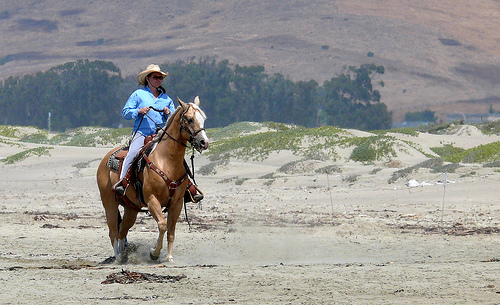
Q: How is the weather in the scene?
A: It is cloudy.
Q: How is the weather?
A: It is cloudy.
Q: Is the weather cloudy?
A: Yes, it is cloudy.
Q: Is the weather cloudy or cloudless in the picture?
A: It is cloudy.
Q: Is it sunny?
A: No, it is cloudy.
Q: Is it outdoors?
A: Yes, it is outdoors.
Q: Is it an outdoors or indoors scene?
A: It is outdoors.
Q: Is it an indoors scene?
A: No, it is outdoors.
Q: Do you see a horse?
A: Yes, there is a horse.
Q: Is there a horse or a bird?
A: Yes, there is a horse.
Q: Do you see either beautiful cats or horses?
A: Yes, there is a beautiful horse.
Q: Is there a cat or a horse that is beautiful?
A: Yes, the horse is beautiful.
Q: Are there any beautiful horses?
A: Yes, there is a beautiful horse.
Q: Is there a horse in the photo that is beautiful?
A: Yes, there is a horse that is beautiful.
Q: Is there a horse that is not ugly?
A: Yes, there is an beautiful horse.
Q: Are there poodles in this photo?
A: No, there are no poodles.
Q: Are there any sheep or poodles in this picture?
A: No, there are no poodles or sheep.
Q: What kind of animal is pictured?
A: The animal is a horse.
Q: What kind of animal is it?
A: The animal is a horse.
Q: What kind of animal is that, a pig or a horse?
A: This is a horse.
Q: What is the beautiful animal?
A: The animal is a horse.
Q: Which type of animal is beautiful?
A: The animal is a horse.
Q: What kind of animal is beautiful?
A: The animal is a horse.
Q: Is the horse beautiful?
A: Yes, the horse is beautiful.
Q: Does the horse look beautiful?
A: Yes, the horse is beautiful.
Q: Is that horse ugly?
A: No, the horse is beautiful.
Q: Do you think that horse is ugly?
A: No, the horse is beautiful.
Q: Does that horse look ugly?
A: No, the horse is beautiful.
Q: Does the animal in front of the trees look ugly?
A: No, the horse is beautiful.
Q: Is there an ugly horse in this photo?
A: No, there is a horse but it is beautiful.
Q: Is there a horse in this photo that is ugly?
A: No, there is a horse but it is beautiful.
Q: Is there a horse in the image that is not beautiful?
A: No, there is a horse but it is beautiful.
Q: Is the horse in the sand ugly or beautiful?
A: The horse is beautiful.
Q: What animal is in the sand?
A: The animal is a horse.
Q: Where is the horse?
A: The horse is in the sand.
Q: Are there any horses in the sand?
A: Yes, there is a horse in the sand.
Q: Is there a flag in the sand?
A: No, there is a horse in the sand.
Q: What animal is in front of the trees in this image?
A: The horse is in front of the trees.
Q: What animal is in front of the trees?
A: The horse is in front of the trees.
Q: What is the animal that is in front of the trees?
A: The animal is a horse.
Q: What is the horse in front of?
A: The horse is in front of the trees.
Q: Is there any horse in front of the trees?
A: Yes, there is a horse in front of the trees.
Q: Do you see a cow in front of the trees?
A: No, there is a horse in front of the trees.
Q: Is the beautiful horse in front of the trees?
A: Yes, the horse is in front of the trees.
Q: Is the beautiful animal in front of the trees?
A: Yes, the horse is in front of the trees.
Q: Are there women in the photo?
A: Yes, there is a woman.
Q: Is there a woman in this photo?
A: Yes, there is a woman.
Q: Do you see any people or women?
A: Yes, there is a woman.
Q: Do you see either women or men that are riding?
A: Yes, the woman is riding.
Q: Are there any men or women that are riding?
A: Yes, the woman is riding.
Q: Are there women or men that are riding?
A: Yes, the woman is riding.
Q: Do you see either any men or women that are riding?
A: Yes, the woman is riding.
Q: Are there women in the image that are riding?
A: Yes, there is a woman that is riding.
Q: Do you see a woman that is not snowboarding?
A: Yes, there is a woman that is riding .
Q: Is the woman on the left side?
A: Yes, the woman is on the left of the image.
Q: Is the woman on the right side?
A: No, the woman is on the left of the image.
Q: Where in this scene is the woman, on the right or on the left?
A: The woman is on the left of the image.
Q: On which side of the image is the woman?
A: The woman is on the left of the image.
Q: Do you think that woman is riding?
A: Yes, the woman is riding.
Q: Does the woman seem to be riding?
A: Yes, the woman is riding.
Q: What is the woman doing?
A: The woman is riding.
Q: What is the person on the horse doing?
A: The woman is riding.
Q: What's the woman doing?
A: The woman is riding.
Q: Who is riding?
A: The woman is riding.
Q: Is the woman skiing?
A: No, the woman is riding.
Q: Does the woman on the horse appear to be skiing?
A: No, the woman is riding.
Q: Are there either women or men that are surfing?
A: No, there is a woman but she is riding.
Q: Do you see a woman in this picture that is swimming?
A: No, there is a woman but she is riding.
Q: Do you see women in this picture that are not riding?
A: No, there is a woman but she is riding.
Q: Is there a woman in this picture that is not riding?
A: No, there is a woman but she is riding.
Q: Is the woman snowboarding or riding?
A: The woman is riding.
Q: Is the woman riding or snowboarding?
A: The woman is riding.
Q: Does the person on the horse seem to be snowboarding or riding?
A: The woman is riding.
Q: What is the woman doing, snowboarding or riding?
A: The woman is riding.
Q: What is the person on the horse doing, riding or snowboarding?
A: The woman is riding.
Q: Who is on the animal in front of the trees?
A: The woman is on the horse.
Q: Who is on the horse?
A: The woman is on the horse.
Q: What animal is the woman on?
A: The woman is on the horse.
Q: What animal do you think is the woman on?
A: The woman is on the horse.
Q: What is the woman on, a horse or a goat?
A: The woman is on a horse.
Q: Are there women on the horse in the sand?
A: Yes, there is a woman on the horse.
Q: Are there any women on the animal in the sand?
A: Yes, there is a woman on the horse.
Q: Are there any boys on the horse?
A: No, there is a woman on the horse.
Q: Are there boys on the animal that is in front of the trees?
A: No, there is a woman on the horse.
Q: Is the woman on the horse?
A: Yes, the woman is on the horse.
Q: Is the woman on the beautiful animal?
A: Yes, the woman is on the horse.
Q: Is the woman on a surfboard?
A: No, the woman is on the horse.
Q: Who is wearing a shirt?
A: The woman is wearing a shirt.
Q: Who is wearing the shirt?
A: The woman is wearing a shirt.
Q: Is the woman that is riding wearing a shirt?
A: Yes, the woman is wearing a shirt.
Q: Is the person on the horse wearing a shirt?
A: Yes, the woman is wearing a shirt.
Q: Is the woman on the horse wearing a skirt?
A: No, the woman is wearing a shirt.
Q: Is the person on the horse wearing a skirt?
A: No, the woman is wearing a shirt.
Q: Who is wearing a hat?
A: The woman is wearing a hat.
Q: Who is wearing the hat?
A: The woman is wearing a hat.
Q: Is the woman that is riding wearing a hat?
A: Yes, the woman is wearing a hat.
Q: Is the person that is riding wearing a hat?
A: Yes, the woman is wearing a hat.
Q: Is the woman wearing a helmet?
A: No, the woman is wearing a hat.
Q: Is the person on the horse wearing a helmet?
A: No, the woman is wearing a hat.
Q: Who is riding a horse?
A: The woman is riding a horse.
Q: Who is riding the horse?
A: The woman is riding a horse.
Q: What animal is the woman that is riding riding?
A: The woman is riding a horse.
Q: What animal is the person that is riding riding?
A: The woman is riding a horse.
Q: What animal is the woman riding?
A: The woman is riding a horse.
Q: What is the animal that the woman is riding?
A: The animal is a horse.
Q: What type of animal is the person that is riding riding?
A: The woman is riding a horse.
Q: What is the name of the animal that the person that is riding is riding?
A: The animal is a horse.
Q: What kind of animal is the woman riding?
A: The woman is riding a horse.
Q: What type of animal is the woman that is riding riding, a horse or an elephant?
A: The woman is riding a horse.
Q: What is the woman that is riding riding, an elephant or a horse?
A: The woman is riding a horse.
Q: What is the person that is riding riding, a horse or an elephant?
A: The woman is riding a horse.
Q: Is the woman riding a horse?
A: Yes, the woman is riding a horse.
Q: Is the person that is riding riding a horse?
A: Yes, the woman is riding a horse.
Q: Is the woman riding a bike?
A: No, the woman is riding a horse.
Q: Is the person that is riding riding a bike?
A: No, the woman is riding a horse.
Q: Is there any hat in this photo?
A: Yes, there is a hat.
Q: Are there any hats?
A: Yes, there is a hat.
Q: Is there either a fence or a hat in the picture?
A: Yes, there is a hat.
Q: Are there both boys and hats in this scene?
A: No, there is a hat but no boys.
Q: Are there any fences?
A: No, there are no fences.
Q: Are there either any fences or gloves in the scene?
A: No, there are no fences or gloves.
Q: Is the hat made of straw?
A: Yes, the hat is made of straw.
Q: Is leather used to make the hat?
A: No, the hat is made of straw.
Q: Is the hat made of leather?
A: No, the hat is made of straw.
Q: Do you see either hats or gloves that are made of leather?
A: No, there is a hat but it is made of straw.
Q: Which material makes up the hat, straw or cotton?
A: The hat is made of straw.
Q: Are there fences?
A: No, there are no fences.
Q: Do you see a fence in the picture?
A: No, there are no fences.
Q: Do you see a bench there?
A: No, there are no benches.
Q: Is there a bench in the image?
A: No, there are no benches.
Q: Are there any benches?
A: No, there are no benches.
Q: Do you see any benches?
A: No, there are no benches.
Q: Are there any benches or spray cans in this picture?
A: No, there are no benches or spray cans.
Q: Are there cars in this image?
A: No, there are no cars.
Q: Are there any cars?
A: No, there are no cars.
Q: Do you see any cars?
A: No, there are no cars.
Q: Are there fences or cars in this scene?
A: No, there are no cars or fences.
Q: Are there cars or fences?
A: No, there are no cars or fences.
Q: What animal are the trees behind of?
A: The trees are behind the horse.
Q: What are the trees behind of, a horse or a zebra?
A: The trees are behind a horse.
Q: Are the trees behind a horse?
A: Yes, the trees are behind a horse.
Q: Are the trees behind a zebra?
A: No, the trees are behind a horse.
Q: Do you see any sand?
A: Yes, there is sand.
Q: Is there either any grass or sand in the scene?
A: Yes, there is sand.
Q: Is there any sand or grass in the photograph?
A: Yes, there is sand.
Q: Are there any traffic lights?
A: No, there are no traffic lights.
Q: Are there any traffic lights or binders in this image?
A: No, there are no traffic lights or binders.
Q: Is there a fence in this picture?
A: No, there are no fences.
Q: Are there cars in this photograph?
A: No, there are no cars.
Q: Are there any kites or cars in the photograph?
A: No, there are no cars or kites.